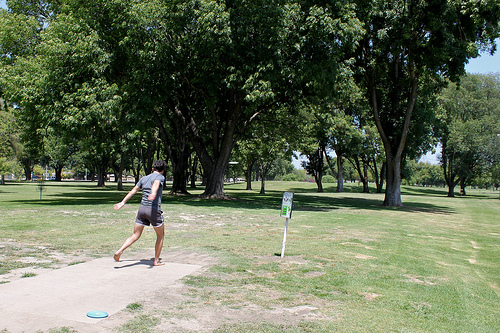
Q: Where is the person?
A: At the park.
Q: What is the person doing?
A: Running.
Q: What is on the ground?
A: Frisbee.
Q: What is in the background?
A: Trees.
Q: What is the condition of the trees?
A: They are green.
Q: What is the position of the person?
A: Standing.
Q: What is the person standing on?
A: Concrete.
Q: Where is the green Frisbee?
A: Behind the person.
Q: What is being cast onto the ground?
A: Shadows.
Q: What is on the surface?
A: Grass.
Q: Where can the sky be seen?
A: Through the trees.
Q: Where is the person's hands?
A: Behind the person.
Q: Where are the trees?
A: In the park.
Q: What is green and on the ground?
A: Grass.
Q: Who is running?
A: The person.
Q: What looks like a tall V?
A: The tree trunk.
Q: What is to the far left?
A: A tree.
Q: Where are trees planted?
A: In the ground,.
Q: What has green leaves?
A: The trees.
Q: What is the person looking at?
A: The trees.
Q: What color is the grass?
A: Green.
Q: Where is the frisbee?
A: On the ground.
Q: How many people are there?
A: 1.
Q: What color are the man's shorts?
A: Black.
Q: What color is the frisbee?
A: Blue.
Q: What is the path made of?
A: Dirt.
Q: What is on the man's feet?
A: Nothing.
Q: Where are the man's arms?
A: Behind him.